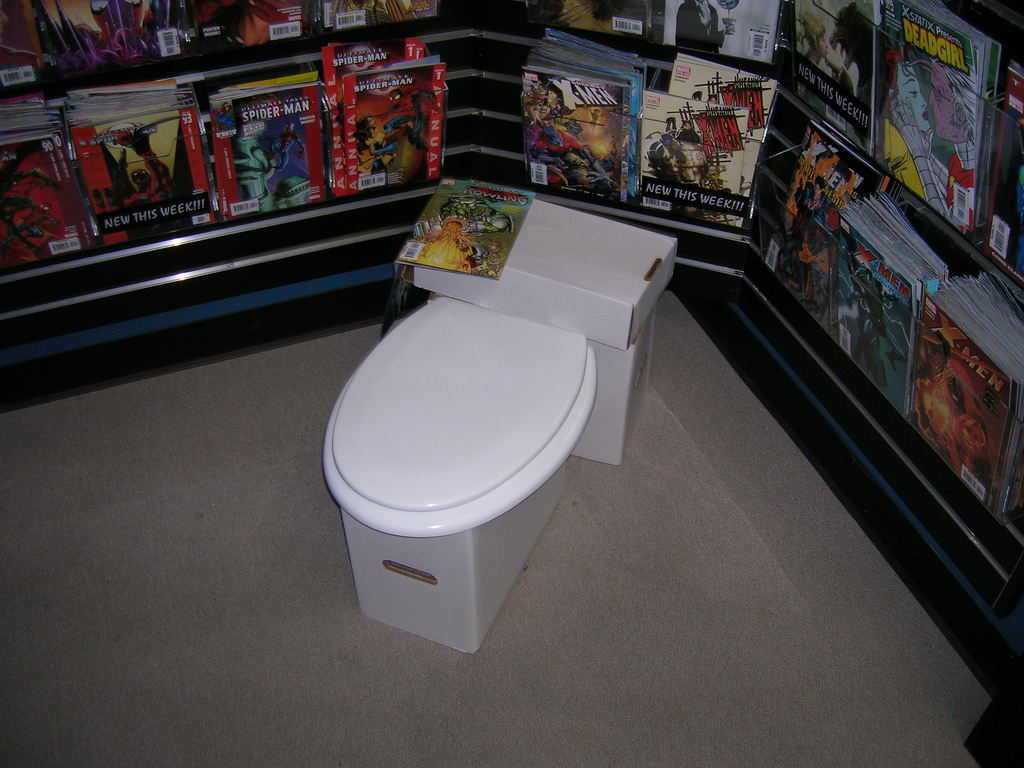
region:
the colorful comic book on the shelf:
[73, 105, 217, 241]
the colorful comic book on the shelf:
[207, 77, 326, 213]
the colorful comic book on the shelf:
[340, 55, 440, 192]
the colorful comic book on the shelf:
[519, 57, 638, 203]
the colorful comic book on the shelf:
[636, 86, 753, 230]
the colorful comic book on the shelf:
[766, 112, 884, 313]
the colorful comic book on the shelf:
[832, 197, 918, 413]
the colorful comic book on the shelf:
[876, 3, 993, 232]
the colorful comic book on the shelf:
[788, 6, 878, 149]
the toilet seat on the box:
[317, 297, 602, 539]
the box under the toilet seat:
[342, 467, 567, 652]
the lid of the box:
[418, 198, 681, 347]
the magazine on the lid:
[396, 180, 539, 280]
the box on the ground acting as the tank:
[568, 313, 655, 466]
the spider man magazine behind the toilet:
[311, 38, 449, 197]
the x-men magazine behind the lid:
[527, 66, 630, 200]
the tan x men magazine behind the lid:
[642, 92, 747, 233]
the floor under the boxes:
[2, 287, 992, 766]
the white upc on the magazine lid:
[399, 237, 429, 261]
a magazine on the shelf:
[926, 236, 1019, 429]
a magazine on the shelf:
[920, 299, 1015, 394]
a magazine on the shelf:
[690, 122, 814, 288]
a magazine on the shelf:
[164, 65, 398, 258]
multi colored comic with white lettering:
[516, 59, 635, 209]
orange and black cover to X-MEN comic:
[900, 274, 1021, 524]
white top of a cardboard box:
[401, 181, 677, 349]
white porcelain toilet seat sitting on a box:
[319, 289, 596, 657]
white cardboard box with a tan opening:
[337, 447, 575, 662]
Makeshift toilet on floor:
[306, 181, 714, 687]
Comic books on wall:
[0, 2, 1015, 451]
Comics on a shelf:
[520, 26, 638, 194]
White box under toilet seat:
[310, 437, 598, 660]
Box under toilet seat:
[337, 411, 566, 659]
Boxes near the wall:
[446, 196, 685, 495]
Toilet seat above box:
[318, 279, 625, 526]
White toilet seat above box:
[305, 287, 647, 499]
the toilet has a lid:
[295, 270, 609, 673]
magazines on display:
[203, 70, 331, 231]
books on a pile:
[831, 182, 949, 410]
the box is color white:
[495, 185, 684, 477]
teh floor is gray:
[571, 519, 881, 760]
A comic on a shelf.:
[340, 54, 458, 190]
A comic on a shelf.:
[498, 57, 620, 206]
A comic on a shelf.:
[623, 80, 764, 235]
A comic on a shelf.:
[659, 58, 771, 145]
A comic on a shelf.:
[825, 217, 930, 411]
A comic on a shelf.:
[332, 65, 457, 186]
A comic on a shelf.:
[518, 59, 642, 197]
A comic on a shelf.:
[631, 74, 775, 233]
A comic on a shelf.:
[663, 51, 774, 141]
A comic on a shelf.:
[757, 115, 888, 332]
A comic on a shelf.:
[903, 307, 1017, 482]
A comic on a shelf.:
[192, 86, 357, 227]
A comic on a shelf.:
[68, 103, 223, 249]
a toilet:
[271, 129, 702, 700]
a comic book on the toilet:
[395, 164, 525, 272]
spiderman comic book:
[319, 48, 453, 203]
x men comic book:
[828, 211, 943, 380]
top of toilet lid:
[313, 345, 602, 538]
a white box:
[403, 174, 666, 339]